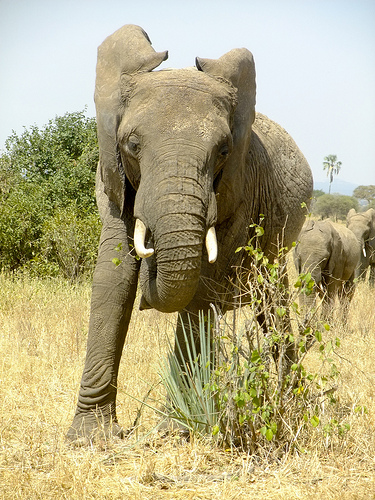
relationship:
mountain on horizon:
[287, 152, 371, 210] [313, 177, 374, 198]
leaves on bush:
[0, 103, 103, 280] [1, 104, 100, 280]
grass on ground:
[1, 273, 372, 499] [252, 49, 273, 91]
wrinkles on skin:
[250, 136, 306, 239] [68, 23, 315, 430]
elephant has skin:
[60, 13, 328, 378] [68, 23, 315, 430]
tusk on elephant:
[202, 225, 221, 262] [51, 14, 312, 470]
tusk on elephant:
[133, 218, 154, 258] [295, 217, 360, 333]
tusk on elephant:
[133, 218, 154, 258] [51, 14, 312, 470]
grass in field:
[179, 223, 341, 457] [3, 214, 373, 500]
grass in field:
[259, 317, 366, 397] [28, 300, 356, 432]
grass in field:
[334, 330, 375, 448] [3, 214, 373, 500]